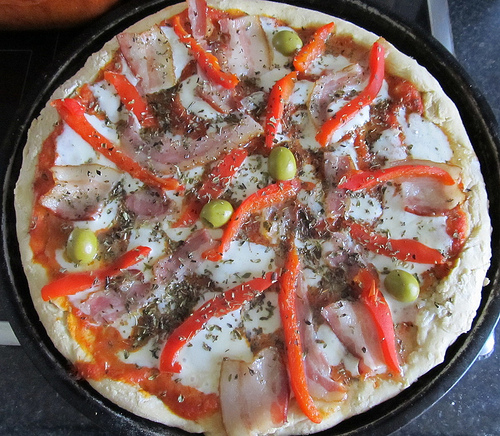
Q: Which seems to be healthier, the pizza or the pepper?
A: The pepper is healthier than the pizza.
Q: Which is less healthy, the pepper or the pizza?
A: The pizza is less healthy than the pepper.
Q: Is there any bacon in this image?
A: Yes, there is bacon.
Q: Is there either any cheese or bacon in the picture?
A: Yes, there is bacon.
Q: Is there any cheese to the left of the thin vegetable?
A: No, there is bacon to the left of the vegetable.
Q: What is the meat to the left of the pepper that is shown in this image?
A: The meat is bacon.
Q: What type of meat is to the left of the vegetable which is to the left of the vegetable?
A: The meat is bacon.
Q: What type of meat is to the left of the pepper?
A: The meat is bacon.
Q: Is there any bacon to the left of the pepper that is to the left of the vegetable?
A: Yes, there is bacon to the left of the pepper.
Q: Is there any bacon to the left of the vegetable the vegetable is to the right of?
A: Yes, there is bacon to the left of the pepper.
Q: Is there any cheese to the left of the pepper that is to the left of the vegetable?
A: No, there is bacon to the left of the pepper.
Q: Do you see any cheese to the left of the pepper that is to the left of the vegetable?
A: No, there is bacon to the left of the pepper.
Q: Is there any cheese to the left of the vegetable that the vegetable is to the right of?
A: No, there is bacon to the left of the pepper.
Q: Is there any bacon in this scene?
A: Yes, there is bacon.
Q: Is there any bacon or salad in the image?
A: Yes, there is bacon.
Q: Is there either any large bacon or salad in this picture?
A: Yes, there is large bacon.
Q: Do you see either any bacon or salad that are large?
A: Yes, the bacon is large.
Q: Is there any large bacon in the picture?
A: Yes, there is large bacon.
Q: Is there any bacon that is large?
A: Yes, there is bacon that is large.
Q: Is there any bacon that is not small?
A: Yes, there is large bacon.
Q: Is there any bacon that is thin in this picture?
A: Yes, there is thin bacon.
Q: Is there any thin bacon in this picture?
A: Yes, there is thin bacon.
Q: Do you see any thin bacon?
A: Yes, there is thin bacon.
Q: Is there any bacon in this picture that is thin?
A: Yes, there is bacon that is thin.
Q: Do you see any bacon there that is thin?
A: Yes, there is bacon that is thin.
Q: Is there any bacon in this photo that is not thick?
A: Yes, there is thin bacon.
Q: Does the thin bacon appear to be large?
A: Yes, the bacon is large.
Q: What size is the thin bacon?
A: The bacon is large.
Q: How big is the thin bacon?
A: The bacon is large.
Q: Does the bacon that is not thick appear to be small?
A: No, the bacon is large.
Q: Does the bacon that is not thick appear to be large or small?
A: The bacon is large.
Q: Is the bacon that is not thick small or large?
A: The bacon is large.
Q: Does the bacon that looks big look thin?
A: Yes, the bacon is thin.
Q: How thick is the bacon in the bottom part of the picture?
A: The bacon is thin.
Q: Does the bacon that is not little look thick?
A: No, the bacon is thin.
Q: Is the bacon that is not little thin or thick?
A: The bacon is thin.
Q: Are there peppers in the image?
A: Yes, there is a pepper.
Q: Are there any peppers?
A: Yes, there is a pepper.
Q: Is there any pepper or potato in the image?
A: Yes, there is a pepper.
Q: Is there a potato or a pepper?
A: Yes, there is a pepper.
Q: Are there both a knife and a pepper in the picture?
A: No, there is a pepper but no knives.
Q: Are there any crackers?
A: No, there are no crackers.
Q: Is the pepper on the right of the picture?
A: Yes, the pepper is on the right of the image.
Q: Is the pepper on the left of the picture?
A: No, the pepper is on the right of the image.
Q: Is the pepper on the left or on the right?
A: The pepper is on the right of the image.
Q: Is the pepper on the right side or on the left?
A: The pepper is on the right of the image.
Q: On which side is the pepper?
A: The pepper is on the right of the image.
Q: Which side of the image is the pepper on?
A: The pepper is on the right of the image.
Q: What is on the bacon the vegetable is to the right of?
A: The pepper is on the bacon.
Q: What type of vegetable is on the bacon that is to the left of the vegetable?
A: The vegetable is a pepper.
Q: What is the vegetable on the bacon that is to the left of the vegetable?
A: The vegetable is a pepper.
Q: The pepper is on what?
A: The pepper is on the bacon.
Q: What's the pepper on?
A: The pepper is on the bacon.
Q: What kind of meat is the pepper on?
A: The pepper is on the bacon.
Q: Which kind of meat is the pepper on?
A: The pepper is on the bacon.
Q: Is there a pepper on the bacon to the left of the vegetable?
A: Yes, there is a pepper on the bacon.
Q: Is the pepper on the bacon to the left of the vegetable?
A: Yes, the pepper is on the bacon.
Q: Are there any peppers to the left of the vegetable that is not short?
A: Yes, there is a pepper to the left of the vegetable.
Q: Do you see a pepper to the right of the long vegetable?
A: No, the pepper is to the left of the vegetable.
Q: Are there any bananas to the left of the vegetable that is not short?
A: No, there is a pepper to the left of the vegetable.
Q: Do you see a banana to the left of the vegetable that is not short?
A: No, there is a pepper to the left of the vegetable.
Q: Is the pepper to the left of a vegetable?
A: Yes, the pepper is to the left of a vegetable.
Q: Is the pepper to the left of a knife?
A: No, the pepper is to the left of a vegetable.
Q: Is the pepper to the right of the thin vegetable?
A: No, the pepper is to the left of the vegetable.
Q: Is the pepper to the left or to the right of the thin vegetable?
A: The pepper is to the left of the vegetable.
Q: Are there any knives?
A: No, there are no knives.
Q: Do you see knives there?
A: No, there are no knives.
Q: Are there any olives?
A: Yes, there are olives.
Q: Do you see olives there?
A: Yes, there are olives.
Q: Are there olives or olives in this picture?
A: Yes, there are olives.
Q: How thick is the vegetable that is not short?
A: The vegetable is thin.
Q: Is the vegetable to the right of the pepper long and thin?
A: Yes, the vegetable is long and thin.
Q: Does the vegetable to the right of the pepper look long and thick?
A: No, the vegetable is long but thin.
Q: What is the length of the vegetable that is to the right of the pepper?
A: The vegetable is long.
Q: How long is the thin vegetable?
A: The vegetable is long.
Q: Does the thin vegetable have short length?
A: No, the vegetable is long.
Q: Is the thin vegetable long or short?
A: The vegetable is long.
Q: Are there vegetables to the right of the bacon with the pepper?
A: Yes, there is a vegetable to the right of the bacon.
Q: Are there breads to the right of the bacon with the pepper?
A: No, there is a vegetable to the right of the bacon.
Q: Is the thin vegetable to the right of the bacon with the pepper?
A: Yes, the vegetable is to the right of the bacon.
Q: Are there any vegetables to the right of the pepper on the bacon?
A: Yes, there is a vegetable to the right of the pepper.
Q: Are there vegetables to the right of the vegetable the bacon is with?
A: Yes, there is a vegetable to the right of the pepper.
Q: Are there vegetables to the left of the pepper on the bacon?
A: No, the vegetable is to the right of the pepper.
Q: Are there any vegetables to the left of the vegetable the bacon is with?
A: No, the vegetable is to the right of the pepper.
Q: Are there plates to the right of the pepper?
A: No, there is a vegetable to the right of the pepper.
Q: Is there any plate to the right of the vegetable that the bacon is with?
A: No, there is a vegetable to the right of the pepper.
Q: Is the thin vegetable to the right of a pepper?
A: Yes, the vegetable is to the right of a pepper.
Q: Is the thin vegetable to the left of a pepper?
A: No, the vegetable is to the right of a pepper.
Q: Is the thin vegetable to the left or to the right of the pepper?
A: The vegetable is to the right of the pepper.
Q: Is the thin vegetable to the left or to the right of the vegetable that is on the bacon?
A: The vegetable is to the right of the pepper.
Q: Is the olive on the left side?
A: Yes, the olive is on the left of the image.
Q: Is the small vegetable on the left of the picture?
A: Yes, the olive is on the left of the image.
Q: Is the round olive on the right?
A: No, the olive is on the left of the image.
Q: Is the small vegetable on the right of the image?
A: No, the olive is on the left of the image.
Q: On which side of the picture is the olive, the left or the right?
A: The olive is on the left of the image.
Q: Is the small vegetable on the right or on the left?
A: The olive is on the left of the image.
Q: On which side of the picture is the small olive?
A: The olive is on the left of the image.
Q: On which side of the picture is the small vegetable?
A: The olive is on the left of the image.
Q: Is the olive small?
A: Yes, the olive is small.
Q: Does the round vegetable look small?
A: Yes, the olive is small.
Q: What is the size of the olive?
A: The olive is small.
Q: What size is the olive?
A: The olive is small.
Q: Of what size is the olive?
A: The olive is small.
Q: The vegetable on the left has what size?
A: The olive is small.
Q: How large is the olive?
A: The olive is small.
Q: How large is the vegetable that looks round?
A: The olive is small.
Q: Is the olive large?
A: No, the olive is small.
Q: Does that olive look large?
A: No, the olive is small.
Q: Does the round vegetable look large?
A: No, the olive is small.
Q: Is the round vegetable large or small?
A: The olive is small.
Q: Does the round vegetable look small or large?
A: The olive is small.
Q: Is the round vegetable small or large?
A: The olive is small.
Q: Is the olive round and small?
A: Yes, the olive is round and small.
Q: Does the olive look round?
A: Yes, the olive is round.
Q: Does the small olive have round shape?
A: Yes, the olive is round.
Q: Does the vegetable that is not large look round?
A: Yes, the olive is round.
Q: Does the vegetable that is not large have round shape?
A: Yes, the olive is round.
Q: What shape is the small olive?
A: The olive is round.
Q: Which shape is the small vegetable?
A: The olive is round.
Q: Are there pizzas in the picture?
A: Yes, there is a pizza.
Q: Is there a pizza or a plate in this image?
A: Yes, there is a pizza.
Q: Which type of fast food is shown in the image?
A: The fast food is a pizza.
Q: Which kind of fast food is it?
A: The food is a pizza.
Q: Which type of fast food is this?
A: This is a pizza.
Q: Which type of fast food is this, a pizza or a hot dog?
A: This is a pizza.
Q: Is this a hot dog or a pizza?
A: This is a pizza.